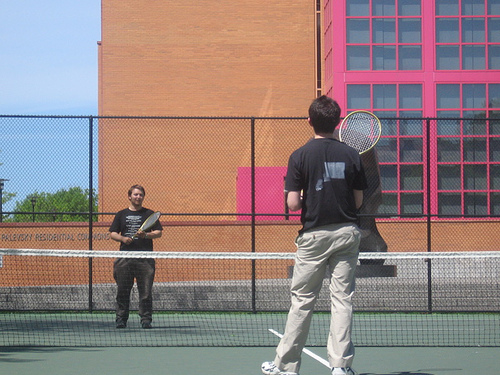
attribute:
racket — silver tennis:
[328, 104, 393, 156]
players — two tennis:
[112, 90, 386, 360]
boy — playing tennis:
[244, 97, 395, 367]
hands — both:
[119, 225, 148, 237]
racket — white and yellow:
[129, 107, 367, 267]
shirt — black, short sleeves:
[279, 141, 371, 221]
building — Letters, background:
[85, 8, 484, 268]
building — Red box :
[232, 160, 318, 220]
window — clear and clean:
[343, 5, 426, 62]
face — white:
[126, 186, 146, 206]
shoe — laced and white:
[140, 309, 159, 330]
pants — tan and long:
[272, 225, 370, 373]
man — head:
[295, 96, 353, 136]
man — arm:
[285, 176, 304, 214]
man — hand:
[110, 222, 154, 244]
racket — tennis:
[132, 206, 168, 241]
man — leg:
[255, 263, 324, 361]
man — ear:
[308, 112, 322, 131]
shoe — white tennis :
[258, 353, 286, 373]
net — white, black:
[13, 242, 484, 342]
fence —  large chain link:
[11, 248, 479, 356]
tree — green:
[31, 190, 99, 225]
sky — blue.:
[26, 23, 71, 78]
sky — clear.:
[24, 12, 90, 91]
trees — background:
[12, 13, 81, 102]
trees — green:
[2, 182, 99, 221]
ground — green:
[0, 310, 497, 372]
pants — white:
[275, 219, 362, 369]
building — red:
[234, 4, 499, 223]